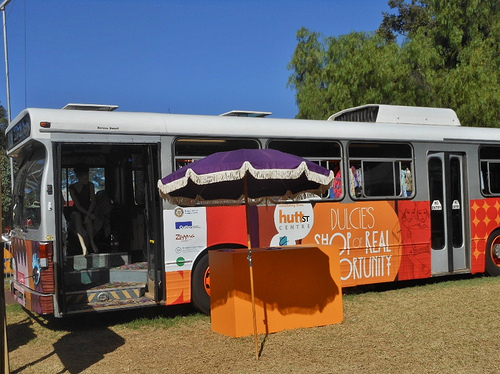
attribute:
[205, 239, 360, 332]
booth — orange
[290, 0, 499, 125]
tree — green, leafy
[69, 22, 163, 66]
sky — clear, blue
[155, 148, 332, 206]
umbrella — purple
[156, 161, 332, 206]
fringe — white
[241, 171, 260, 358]
pole — white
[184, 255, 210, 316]
wheel — black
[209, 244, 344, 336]
stand — orange, wooden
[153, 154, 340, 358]
umbrella — purple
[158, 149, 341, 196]
umbrella — blue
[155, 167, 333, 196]
trim — white, fringed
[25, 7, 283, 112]
sky — blue